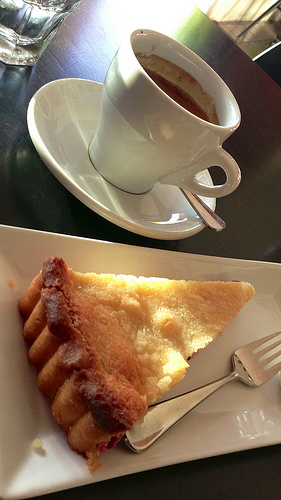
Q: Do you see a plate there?
A: Yes, there is a plate.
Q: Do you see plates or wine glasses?
A: Yes, there is a plate.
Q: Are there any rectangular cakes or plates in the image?
A: Yes, there is a rectangular plate.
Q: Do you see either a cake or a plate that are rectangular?
A: Yes, the plate is rectangular.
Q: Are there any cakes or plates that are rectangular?
A: Yes, the plate is rectangular.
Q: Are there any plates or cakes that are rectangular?
A: Yes, the plate is rectangular.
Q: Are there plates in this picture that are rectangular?
A: Yes, there is a rectangular plate.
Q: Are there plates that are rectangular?
A: Yes, there is a plate that is rectangular.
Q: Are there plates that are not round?
A: Yes, there is a rectangular plate.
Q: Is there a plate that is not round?
A: Yes, there is a rectangular plate.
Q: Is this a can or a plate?
A: This is a plate.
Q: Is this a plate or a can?
A: This is a plate.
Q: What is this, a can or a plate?
A: This is a plate.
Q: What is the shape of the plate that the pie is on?
A: The plate is rectangular.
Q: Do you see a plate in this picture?
A: Yes, there is a plate.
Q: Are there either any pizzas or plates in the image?
A: Yes, there is a plate.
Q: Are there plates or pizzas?
A: Yes, there is a plate.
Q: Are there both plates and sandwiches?
A: No, there is a plate but no sandwiches.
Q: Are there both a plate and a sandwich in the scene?
A: No, there is a plate but no sandwiches.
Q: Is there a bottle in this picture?
A: No, there are no bottles.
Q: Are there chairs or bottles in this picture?
A: No, there are no bottles or chairs.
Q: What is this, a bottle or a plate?
A: This is a plate.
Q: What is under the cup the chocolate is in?
A: The plate is under the cup.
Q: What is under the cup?
A: The plate is under the cup.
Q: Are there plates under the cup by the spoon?
A: Yes, there is a plate under the cup.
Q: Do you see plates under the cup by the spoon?
A: Yes, there is a plate under the cup.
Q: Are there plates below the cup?
A: Yes, there is a plate below the cup.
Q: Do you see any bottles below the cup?
A: No, there is a plate below the cup.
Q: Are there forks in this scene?
A: Yes, there is a fork.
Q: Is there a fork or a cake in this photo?
A: Yes, there is a fork.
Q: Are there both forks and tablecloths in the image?
A: No, there is a fork but no tablecloths.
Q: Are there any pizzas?
A: No, there are no pizzas.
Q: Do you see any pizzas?
A: No, there are no pizzas.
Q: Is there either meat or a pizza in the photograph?
A: No, there are no pizzas or meat.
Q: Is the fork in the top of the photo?
A: No, the fork is in the bottom of the image.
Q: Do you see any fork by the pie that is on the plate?
A: Yes, there is a fork by the pie.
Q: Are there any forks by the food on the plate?
A: Yes, there is a fork by the pie.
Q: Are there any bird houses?
A: No, there are no bird houses.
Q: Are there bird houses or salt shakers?
A: No, there are no bird houses or salt shakers.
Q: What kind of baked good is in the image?
A: The baked good is a pie.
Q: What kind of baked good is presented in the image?
A: The baked good is a pie.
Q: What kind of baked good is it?
A: The food is a pie.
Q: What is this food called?
A: This is a pie.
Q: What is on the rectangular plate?
A: The pie is on the plate.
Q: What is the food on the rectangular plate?
A: The food is a pie.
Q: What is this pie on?
A: The pie is on the plate.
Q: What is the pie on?
A: The pie is on the plate.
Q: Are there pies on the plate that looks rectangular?
A: Yes, there is a pie on the plate.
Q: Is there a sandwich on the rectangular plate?
A: No, there is a pie on the plate.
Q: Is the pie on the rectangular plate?
A: Yes, the pie is on the plate.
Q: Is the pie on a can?
A: No, the pie is on the plate.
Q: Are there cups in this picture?
A: Yes, there is a cup.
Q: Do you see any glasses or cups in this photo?
A: Yes, there is a cup.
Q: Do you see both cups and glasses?
A: Yes, there are both a cup and glasses.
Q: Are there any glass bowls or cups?
A: Yes, there is a glass cup.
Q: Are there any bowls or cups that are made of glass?
A: Yes, the cup is made of glass.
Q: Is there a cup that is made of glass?
A: Yes, there is a cup that is made of glass.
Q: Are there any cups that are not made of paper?
A: Yes, there is a cup that is made of glass.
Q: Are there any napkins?
A: No, there are no napkins.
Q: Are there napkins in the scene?
A: No, there are no napkins.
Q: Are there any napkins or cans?
A: No, there are no napkins or cans.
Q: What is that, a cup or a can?
A: That is a cup.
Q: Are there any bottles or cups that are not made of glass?
A: No, there is a cup but it is made of glass.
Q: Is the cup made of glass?
A: Yes, the cup is made of glass.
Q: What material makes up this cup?
A: The cup is made of glass.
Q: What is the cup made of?
A: The cup is made of glass.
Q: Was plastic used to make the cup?
A: No, the cup is made of glass.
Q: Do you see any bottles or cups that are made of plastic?
A: No, there is a cup but it is made of glass.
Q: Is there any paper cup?
A: No, there is a cup but it is made of glass.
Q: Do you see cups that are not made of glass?
A: No, there is a cup but it is made of glass.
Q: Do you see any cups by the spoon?
A: Yes, there is a cup by the spoon.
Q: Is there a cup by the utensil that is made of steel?
A: Yes, there is a cup by the spoon.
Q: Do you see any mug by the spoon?
A: No, there is a cup by the spoon.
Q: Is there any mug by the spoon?
A: No, there is a cup by the spoon.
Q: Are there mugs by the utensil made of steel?
A: No, there is a cup by the spoon.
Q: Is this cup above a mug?
A: No, the cup is above the plate.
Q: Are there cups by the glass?
A: Yes, there is a cup by the glass.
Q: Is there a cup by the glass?
A: Yes, there is a cup by the glass.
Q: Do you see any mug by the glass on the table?
A: No, there is a cup by the glass.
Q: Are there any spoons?
A: Yes, there is a spoon.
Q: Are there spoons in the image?
A: Yes, there is a spoon.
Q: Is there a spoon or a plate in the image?
A: Yes, there is a spoon.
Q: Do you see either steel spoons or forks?
A: Yes, there is a steel spoon.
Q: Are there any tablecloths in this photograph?
A: No, there are no tablecloths.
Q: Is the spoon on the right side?
A: Yes, the spoon is on the right of the image.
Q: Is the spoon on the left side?
A: No, the spoon is on the right of the image.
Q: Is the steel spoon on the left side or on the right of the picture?
A: The spoon is on the right of the image.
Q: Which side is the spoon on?
A: The spoon is on the right of the image.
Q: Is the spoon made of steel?
A: Yes, the spoon is made of steel.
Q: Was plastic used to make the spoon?
A: No, the spoon is made of steel.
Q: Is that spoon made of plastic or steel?
A: The spoon is made of steel.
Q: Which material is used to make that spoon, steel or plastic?
A: The spoon is made of steel.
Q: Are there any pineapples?
A: No, there are no pineapples.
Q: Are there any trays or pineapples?
A: No, there are no pineapples or trays.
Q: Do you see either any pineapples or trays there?
A: No, there are no pineapples or trays.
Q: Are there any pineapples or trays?
A: No, there are no pineapples or trays.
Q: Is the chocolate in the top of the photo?
A: Yes, the chocolate is in the top of the image.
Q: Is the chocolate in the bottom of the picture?
A: No, the chocolate is in the top of the image.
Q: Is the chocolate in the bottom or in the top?
A: The chocolate is in the top of the image.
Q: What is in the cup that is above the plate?
A: The chocolate is in the cup.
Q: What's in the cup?
A: The chocolate is in the cup.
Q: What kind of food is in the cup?
A: The food is chocolate.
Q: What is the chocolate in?
A: The chocolate is in the cup.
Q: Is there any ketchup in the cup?
A: No, there is chocolate in the cup.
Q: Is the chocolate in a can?
A: No, the chocolate is in the cup.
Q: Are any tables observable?
A: Yes, there is a table.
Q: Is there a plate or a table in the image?
A: Yes, there is a table.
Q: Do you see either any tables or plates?
A: Yes, there is a table.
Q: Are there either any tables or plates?
A: Yes, there is a table.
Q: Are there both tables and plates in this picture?
A: Yes, there are both a table and a plate.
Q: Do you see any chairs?
A: No, there are no chairs.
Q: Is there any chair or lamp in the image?
A: No, there are no chairs or lamps.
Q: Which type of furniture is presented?
A: The furniture is a table.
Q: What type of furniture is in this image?
A: The furniture is a table.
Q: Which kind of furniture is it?
A: The piece of furniture is a table.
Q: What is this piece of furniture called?
A: This is a table.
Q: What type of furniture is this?
A: This is a table.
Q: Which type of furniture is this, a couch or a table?
A: This is a table.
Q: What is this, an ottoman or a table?
A: This is a table.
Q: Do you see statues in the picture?
A: No, there are no statues.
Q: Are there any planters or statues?
A: No, there are no statues or planters.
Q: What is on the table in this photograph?
A: The glass is on the table.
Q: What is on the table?
A: The glass is on the table.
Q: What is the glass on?
A: The glass is on the table.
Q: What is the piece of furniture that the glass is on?
A: The piece of furniture is a table.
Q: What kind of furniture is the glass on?
A: The glass is on the table.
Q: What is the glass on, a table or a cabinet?
A: The glass is on a table.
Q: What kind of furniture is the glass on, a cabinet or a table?
A: The glass is on a table.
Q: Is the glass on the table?
A: Yes, the glass is on the table.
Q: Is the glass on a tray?
A: No, the glass is on the table.